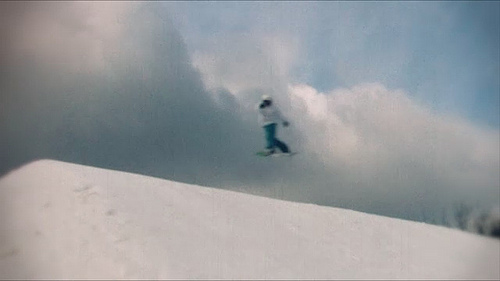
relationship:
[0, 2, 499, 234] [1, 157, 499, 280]
cloud on top of mountain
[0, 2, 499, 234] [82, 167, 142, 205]
cloud near snow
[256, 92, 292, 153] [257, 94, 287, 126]
man wearing hoodie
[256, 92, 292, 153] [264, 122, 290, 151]
man wearing pants